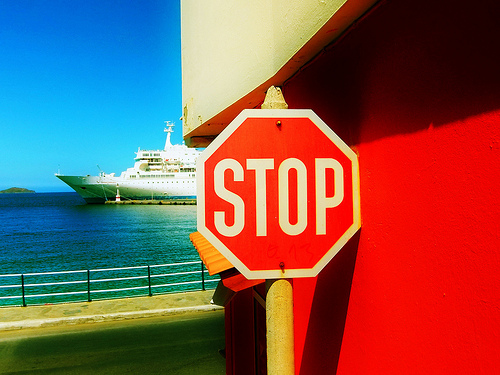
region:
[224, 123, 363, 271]
A red stop sign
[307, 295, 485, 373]
A red house wall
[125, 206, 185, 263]
A blue water surface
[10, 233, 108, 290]
A blue water surface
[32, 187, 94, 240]
A blue water surface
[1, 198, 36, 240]
A blue water surface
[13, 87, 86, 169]
A light blue sky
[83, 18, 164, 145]
A light blue sky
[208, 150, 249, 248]
This is a letter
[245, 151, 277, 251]
This is a letter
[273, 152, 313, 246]
This is a letter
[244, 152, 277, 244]
This is a letter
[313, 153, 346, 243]
This is a letter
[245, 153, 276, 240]
This is a letter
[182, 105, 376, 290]
red and white stop sign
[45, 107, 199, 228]
large ship in the water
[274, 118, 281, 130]
bolt at the top of the sign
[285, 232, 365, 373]
shadow from the sign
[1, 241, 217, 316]
fence along the shore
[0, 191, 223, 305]
dark blue body of water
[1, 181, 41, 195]
island in the distance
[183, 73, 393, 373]
stop sign on a pole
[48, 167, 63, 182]
tip of the ship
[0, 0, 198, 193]
bright blue sky with no clouds in sight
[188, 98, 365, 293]
red and white stop sign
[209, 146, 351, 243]
white writing in all caps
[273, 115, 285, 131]
bolt at the top of the sign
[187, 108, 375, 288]
white border around the sign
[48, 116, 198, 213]
large ship in the water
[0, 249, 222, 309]
fence along the shore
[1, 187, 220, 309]
dark blue body of water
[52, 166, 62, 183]
tip of the ship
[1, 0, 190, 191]
bright blue sky with no clouds in sight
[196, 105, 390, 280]
A hanging stop sign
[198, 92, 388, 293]
A red and white stop sign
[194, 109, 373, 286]
A stop sign on the wall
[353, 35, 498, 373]
A red colored wall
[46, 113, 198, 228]
A cruise ship on the water